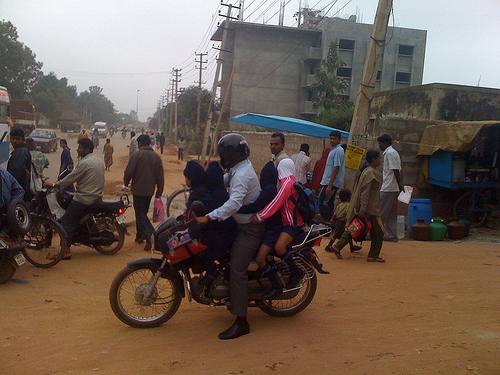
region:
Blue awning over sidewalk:
[237, 101, 344, 135]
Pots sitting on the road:
[412, 217, 473, 248]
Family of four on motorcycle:
[157, 144, 311, 334]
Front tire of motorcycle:
[106, 250, 183, 334]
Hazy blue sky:
[77, 43, 154, 69]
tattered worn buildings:
[391, 33, 427, 85]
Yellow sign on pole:
[346, 138, 366, 170]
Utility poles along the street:
[166, 49, 207, 129]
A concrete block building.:
[198, 12, 432, 190]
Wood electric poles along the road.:
[160, 1, 392, 221]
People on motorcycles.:
[3, 130, 346, 328]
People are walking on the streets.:
[2, 97, 430, 351]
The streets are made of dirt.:
[5, 116, 497, 358]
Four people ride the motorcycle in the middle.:
[124, 126, 336, 331]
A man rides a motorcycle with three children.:
[103, 134, 335, 347]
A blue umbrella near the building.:
[229, 109, 354, 145]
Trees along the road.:
[0, 23, 147, 138]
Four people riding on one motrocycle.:
[203, 140, 306, 295]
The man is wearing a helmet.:
[215, 119, 250, 163]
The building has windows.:
[308, 27, 358, 108]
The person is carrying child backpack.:
[338, 203, 378, 242]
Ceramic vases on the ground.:
[405, 204, 477, 245]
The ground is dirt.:
[330, 263, 476, 364]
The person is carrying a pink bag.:
[143, 190, 169, 226]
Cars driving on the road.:
[17, 104, 67, 155]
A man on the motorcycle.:
[31, 122, 134, 244]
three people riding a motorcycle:
[122, 133, 314, 332]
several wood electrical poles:
[140, 0, 243, 133]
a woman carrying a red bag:
[348, 153, 388, 250]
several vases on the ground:
[410, 209, 470, 240]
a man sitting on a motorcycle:
[52, 130, 107, 250]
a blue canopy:
[235, 101, 362, 138]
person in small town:
[379, 132, 406, 251]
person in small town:
[359, 147, 391, 257]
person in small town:
[321, 126, 340, 220]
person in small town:
[271, 162, 310, 262]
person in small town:
[122, 130, 184, 246]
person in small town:
[152, 130, 174, 160]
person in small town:
[96, 130, 126, 175]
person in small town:
[171, 127, 191, 174]